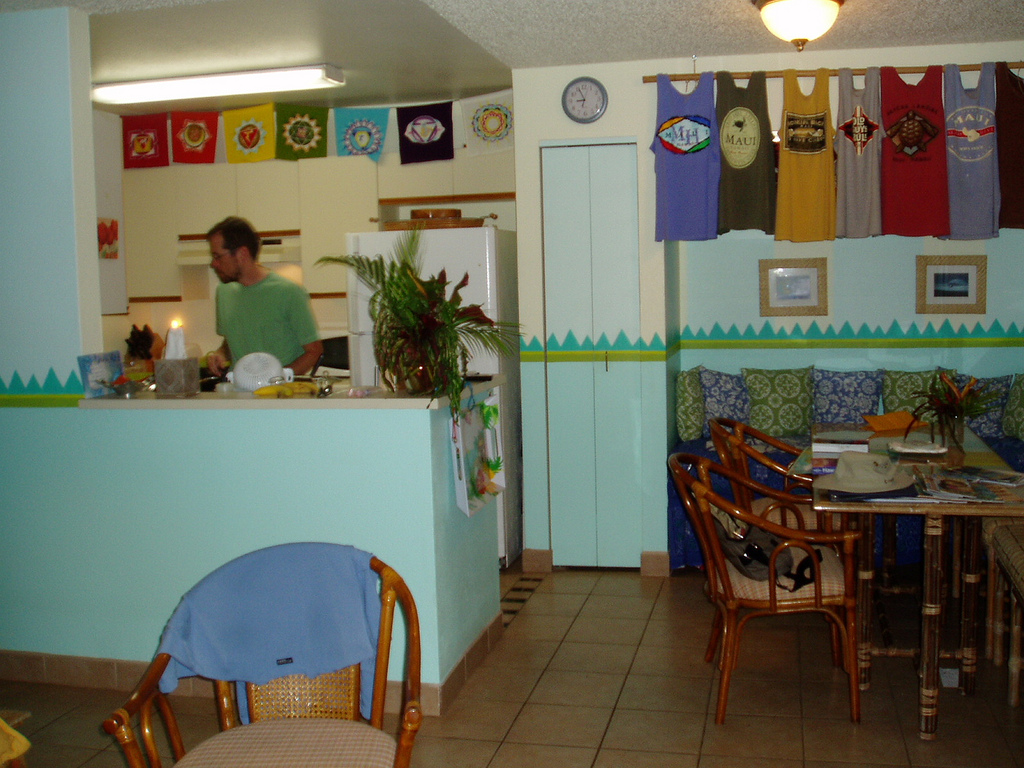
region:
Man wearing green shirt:
[144, 203, 385, 397]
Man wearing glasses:
[174, 205, 330, 395]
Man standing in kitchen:
[196, 212, 343, 380]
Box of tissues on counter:
[145, 326, 213, 396]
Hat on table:
[811, 435, 919, 518]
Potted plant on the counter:
[337, 244, 503, 406]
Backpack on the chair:
[704, 495, 812, 587]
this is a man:
[175, 187, 330, 399]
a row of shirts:
[631, 54, 1017, 260]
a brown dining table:
[807, 376, 1022, 713]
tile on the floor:
[469, 528, 985, 766]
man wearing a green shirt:
[165, 249, 320, 383]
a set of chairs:
[671, 402, 884, 704]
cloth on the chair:
[137, 531, 441, 754]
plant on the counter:
[295, 211, 520, 439]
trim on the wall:
[536, 310, 1021, 384]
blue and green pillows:
[680, 363, 908, 424]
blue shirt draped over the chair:
[153, 530, 400, 696]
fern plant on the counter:
[340, 244, 490, 399]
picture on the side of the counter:
[443, 401, 504, 518]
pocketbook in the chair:
[700, 496, 817, 592]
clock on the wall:
[557, 67, 612, 124]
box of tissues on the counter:
[150, 313, 201, 400]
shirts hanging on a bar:
[636, 70, 1020, 241]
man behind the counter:
[179, 205, 320, 355]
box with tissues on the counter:
[146, 313, 208, 396]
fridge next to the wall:
[346, 221, 499, 278]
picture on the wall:
[751, 249, 835, 320]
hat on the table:
[813, 445, 913, 504]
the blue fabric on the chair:
[102, 540, 422, 766]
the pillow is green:
[675, 360, 702, 443]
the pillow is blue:
[699, 358, 754, 442]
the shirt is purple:
[646, 73, 714, 244]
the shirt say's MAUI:
[713, 70, 771, 236]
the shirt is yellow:
[769, 69, 842, 246]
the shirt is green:
[212, 265, 326, 379]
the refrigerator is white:
[345, 222, 522, 568]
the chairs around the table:
[667, 411, 1022, 741]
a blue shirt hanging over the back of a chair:
[101, 537, 428, 766]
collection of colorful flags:
[116, 89, 525, 170]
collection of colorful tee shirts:
[651, 58, 1021, 240]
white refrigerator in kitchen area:
[335, 218, 522, 574]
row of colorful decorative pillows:
[672, 360, 1021, 455]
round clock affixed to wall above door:
[553, 74, 610, 126]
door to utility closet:
[534, 134, 653, 574]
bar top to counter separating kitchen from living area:
[85, 370, 510, 412]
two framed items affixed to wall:
[749, 247, 996, 324]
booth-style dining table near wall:
[806, 406, 1021, 745]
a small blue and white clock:
[555, 76, 612, 122]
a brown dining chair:
[656, 454, 875, 718]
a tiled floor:
[7, 556, 1020, 763]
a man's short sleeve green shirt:
[200, 271, 322, 373]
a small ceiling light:
[746, 0, 857, 56]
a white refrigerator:
[346, 233, 527, 573]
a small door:
[532, 143, 641, 564]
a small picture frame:
[909, 253, 989, 318]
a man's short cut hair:
[203, 214, 274, 265]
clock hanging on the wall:
[564, 74, 612, 123]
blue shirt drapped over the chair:
[156, 540, 382, 719]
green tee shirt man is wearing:
[213, 272, 321, 364]